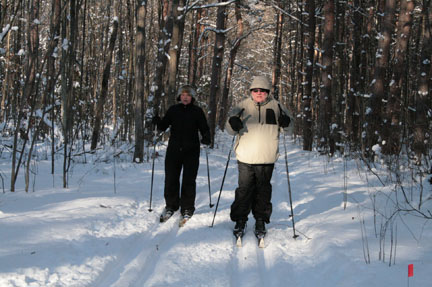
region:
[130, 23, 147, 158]
a tall tree trunk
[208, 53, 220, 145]
a tall tree trunk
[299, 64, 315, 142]
a tall tree trunk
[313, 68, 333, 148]
a tall tree trunk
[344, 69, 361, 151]
a tall tree trunk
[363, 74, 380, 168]
a tall tree trunk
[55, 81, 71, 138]
a tall tree trunk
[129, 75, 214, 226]
a person skating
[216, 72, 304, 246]
a person skating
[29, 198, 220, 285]
cold white ice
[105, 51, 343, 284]
the people are skiing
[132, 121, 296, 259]
the pants are black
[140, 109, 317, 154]
the gloves are black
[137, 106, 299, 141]
the people are wearing gloves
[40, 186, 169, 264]
the snow is white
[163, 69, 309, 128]
the couple is wearing hats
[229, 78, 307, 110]
the man is wearing sunglasses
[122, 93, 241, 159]
the jacket is black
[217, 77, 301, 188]
the jacket is beige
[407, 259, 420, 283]
the flag is red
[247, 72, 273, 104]
the head of the man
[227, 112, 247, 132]
a black glove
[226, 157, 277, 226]
a black pair of pants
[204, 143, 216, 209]
a black ski pole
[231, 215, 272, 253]
a pair of skis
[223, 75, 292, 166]
a gray coat on the man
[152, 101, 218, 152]
a black coat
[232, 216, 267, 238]
a pair of ski boots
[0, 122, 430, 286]
white snow on the ground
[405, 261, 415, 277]
a small red flag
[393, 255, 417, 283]
the flag is red.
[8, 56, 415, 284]
snow covering the ground.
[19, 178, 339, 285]
the snow is white.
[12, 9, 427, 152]
snow is covering the trees.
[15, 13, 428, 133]
the trees are bare.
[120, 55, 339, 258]
a couple skiing together.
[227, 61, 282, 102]
the man is wearing a hat.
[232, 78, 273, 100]
the man is wearing sunglasses.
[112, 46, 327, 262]
the people are holding ski poles.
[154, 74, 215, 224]
the woman is wearing all black.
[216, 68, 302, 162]
A beige and ecru parka with black pocket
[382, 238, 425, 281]
a bright orange trail marker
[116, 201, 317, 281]
cross country skies in the ski paths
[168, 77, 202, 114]
a furry hat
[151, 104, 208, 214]
black snow suit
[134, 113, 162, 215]
ski poles to give balance and help in turns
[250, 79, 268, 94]
one skier wears sunglasses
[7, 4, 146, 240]
snow in the woods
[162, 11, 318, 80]
sun shines on parts of the trees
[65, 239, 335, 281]
ski tracks in the snow